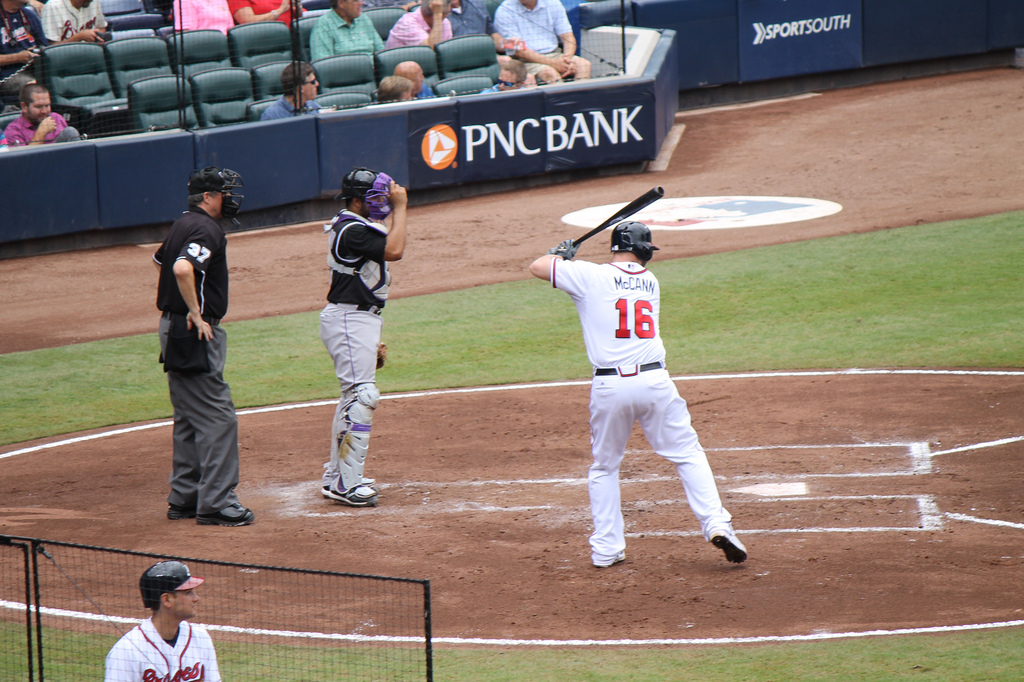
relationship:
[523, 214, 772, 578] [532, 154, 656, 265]
man swinging a bat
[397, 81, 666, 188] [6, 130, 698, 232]
advertisement on wall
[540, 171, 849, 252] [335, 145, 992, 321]
emblems on ground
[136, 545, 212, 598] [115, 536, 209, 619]
hat on head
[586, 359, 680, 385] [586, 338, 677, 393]
belt around waist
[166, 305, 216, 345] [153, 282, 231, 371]
hands on hip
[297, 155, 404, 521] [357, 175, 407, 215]
catcher wearing face mask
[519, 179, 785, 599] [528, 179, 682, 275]
man holding baseball bat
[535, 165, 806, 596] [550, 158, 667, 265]
player holding bat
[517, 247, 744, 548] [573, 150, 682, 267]
man with bat